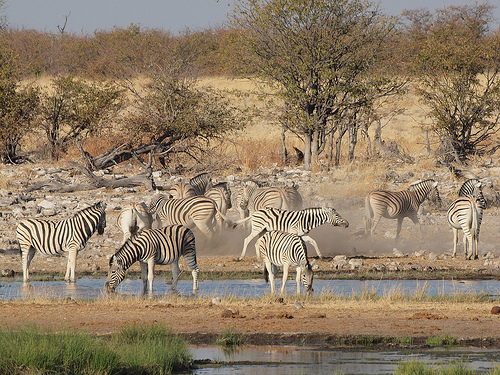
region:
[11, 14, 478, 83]
The trees are dying.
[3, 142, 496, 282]
Several zebras are standing.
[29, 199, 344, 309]
Some zebras are drinking.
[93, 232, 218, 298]
The zebra is black and white.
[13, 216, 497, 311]
They are by water.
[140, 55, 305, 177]
The grass is dying.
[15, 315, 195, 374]
There is some vegetation.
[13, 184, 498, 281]
Several zebras are standing in the dirt.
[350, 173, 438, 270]
The zebra is running.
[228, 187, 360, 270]
The zebra is walking.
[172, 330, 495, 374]
swampy ground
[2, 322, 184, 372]
tall green grass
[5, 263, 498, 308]
a watering hole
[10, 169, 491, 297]
zebra's next to a watering hole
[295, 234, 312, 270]
a black main on a zebra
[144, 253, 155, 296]
a white leg on a zebra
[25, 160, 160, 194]
a dead tree on the ground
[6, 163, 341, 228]
rocky ground behind zebras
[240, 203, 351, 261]
a running zebra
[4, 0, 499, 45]
a gray blue sky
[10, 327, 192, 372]
clump of grass beside stream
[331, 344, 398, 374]
ripples on surface of stream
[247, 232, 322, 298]
zebra drinking from stream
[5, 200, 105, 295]
zebra standing in stream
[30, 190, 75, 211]
grey rocks covering ground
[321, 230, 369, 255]
cloud of dust in air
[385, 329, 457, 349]
small grass growing on stream shore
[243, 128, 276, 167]
brown grass growing in field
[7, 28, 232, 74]
thick trees with brown and green leaves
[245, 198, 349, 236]
zebra running down stream shore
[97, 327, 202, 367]
green grass growing beside pond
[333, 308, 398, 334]
ground covered in brown dirt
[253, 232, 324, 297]
zebra drinking from pond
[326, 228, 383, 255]
dust cloud in air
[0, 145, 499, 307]
large group of zebras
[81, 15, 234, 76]
trees covered in green leaves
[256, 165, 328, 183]
ground covered in large rocks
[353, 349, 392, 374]
ripples on pond water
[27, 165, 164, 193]
log laying on ground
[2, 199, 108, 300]
zebra standing in water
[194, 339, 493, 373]
muddy water near a watering hole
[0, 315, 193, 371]
long green grass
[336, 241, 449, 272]
rocks alongside the watering hole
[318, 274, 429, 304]
tall dry grass by the watering hole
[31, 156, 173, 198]
an old dead tree on the ground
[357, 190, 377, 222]
a white tail ona giraffe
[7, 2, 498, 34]
a dark blue sky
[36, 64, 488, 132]
a dry grassy field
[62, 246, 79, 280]
two white front legs on a zebra